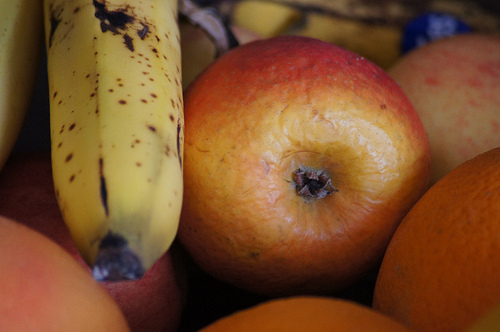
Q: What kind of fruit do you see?
A: Bananas,apples and oranges.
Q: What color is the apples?
A: They are red.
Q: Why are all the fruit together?
A: Because they belong in same food group.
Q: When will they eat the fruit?
A: When hunger.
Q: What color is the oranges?
A: They are orange.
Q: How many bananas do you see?
A: About three.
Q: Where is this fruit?
A: In a bowl.